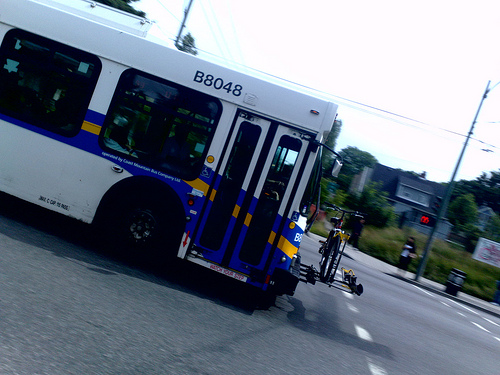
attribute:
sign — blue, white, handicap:
[199, 160, 216, 182]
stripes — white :
[323, 259, 383, 374]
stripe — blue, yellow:
[2, 106, 305, 284]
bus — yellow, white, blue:
[5, 3, 367, 349]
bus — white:
[4, 2, 366, 316]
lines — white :
[337, 292, 393, 373]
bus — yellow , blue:
[0, 14, 460, 353]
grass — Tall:
[320, 170, 499, 293]